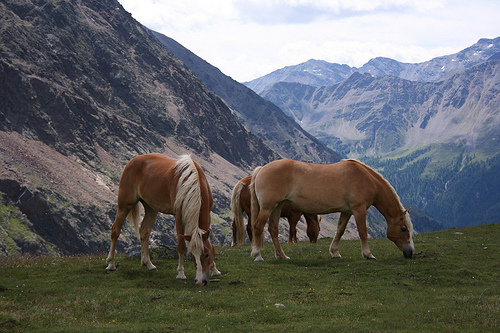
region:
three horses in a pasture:
[76, 138, 443, 277]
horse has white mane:
[105, 141, 225, 291]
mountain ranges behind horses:
[235, 90, 471, 152]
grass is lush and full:
[140, 286, 295, 316]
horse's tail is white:
[226, 175, 251, 255]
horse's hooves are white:
[103, 235, 218, 286]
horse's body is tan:
[266, 160, 376, 225]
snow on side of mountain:
[360, 112, 485, 143]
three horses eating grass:
[95, 140, 440, 288]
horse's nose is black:
[400, 242, 418, 264]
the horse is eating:
[132, 130, 213, 300]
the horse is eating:
[310, 149, 475, 331]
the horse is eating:
[278, 185, 359, 279]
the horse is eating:
[172, 164, 227, 308]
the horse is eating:
[360, 149, 445, 299]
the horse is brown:
[127, 153, 261, 326]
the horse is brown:
[249, 127, 429, 283]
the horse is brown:
[95, 120, 215, 310]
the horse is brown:
[215, 157, 322, 273]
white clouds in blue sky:
[158, 6, 205, 31]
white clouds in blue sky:
[219, 12, 274, 49]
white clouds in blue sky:
[258, 6, 310, 34]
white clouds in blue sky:
[288, 11, 349, 38]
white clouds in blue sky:
[343, 8, 391, 35]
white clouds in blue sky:
[381, 23, 421, 47]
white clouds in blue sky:
[405, 12, 458, 37]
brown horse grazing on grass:
[105, 140, 211, 293]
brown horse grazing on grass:
[238, 151, 415, 251]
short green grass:
[261, 271, 381, 313]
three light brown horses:
[104, 143, 418, 280]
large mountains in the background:
[11, 23, 463, 175]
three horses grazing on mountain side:
[77, 137, 442, 288]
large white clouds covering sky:
[214, 10, 441, 50]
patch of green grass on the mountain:
[51, 232, 476, 320]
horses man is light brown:
[177, 148, 208, 251]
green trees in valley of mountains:
[417, 142, 495, 218]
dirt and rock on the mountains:
[54, 71, 112, 231]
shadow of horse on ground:
[85, 264, 220, 295]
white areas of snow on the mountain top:
[434, 33, 499, 73]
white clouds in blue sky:
[162, 5, 222, 45]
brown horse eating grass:
[97, 142, 222, 292]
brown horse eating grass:
[235, 145, 432, 262]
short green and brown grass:
[27, 275, 80, 308]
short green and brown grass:
[105, 285, 168, 315]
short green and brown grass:
[218, 292, 289, 325]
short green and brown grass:
[291, 261, 346, 291]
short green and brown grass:
[318, 298, 373, 328]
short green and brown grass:
[372, 255, 422, 285]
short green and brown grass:
[428, 247, 498, 311]